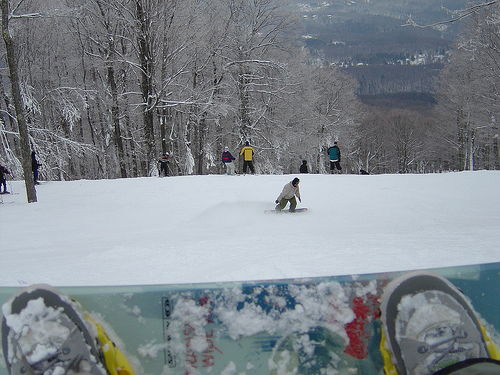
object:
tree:
[3, 2, 40, 201]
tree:
[98, 0, 129, 180]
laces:
[421, 327, 477, 370]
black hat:
[292, 177, 300, 185]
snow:
[0, 3, 500, 173]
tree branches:
[247, 7, 287, 73]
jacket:
[221, 151, 233, 163]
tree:
[436, 40, 469, 162]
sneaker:
[381, 270, 499, 373]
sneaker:
[0, 285, 134, 372]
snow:
[2, 165, 499, 284]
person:
[273, 177, 304, 212]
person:
[327, 140, 344, 173]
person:
[239, 139, 257, 175]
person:
[0, 158, 14, 195]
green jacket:
[324, 145, 343, 162]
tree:
[395, 112, 408, 178]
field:
[0, 4, 498, 286]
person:
[221, 145, 238, 175]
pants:
[223, 160, 238, 174]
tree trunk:
[130, 1, 161, 176]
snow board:
[4, 257, 499, 373]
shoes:
[0, 272, 135, 374]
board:
[262, 207, 311, 213]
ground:
[1, 173, 499, 268]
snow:
[150, 281, 354, 357]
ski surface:
[2, 169, 499, 263]